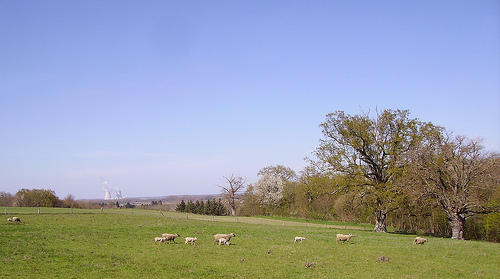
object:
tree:
[393, 130, 500, 241]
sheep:
[413, 237, 429, 245]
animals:
[212, 233, 235, 246]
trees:
[175, 198, 228, 217]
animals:
[154, 232, 201, 245]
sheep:
[294, 237, 308, 244]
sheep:
[336, 233, 356, 246]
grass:
[84, 247, 130, 272]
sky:
[8, 13, 474, 109]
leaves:
[383, 127, 403, 143]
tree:
[295, 105, 462, 234]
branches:
[448, 152, 478, 193]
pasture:
[256, 218, 466, 270]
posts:
[11, 210, 374, 222]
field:
[13, 220, 140, 255]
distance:
[138, 192, 208, 205]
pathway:
[191, 217, 371, 231]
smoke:
[100, 180, 111, 191]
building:
[104, 192, 111, 201]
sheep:
[7, 217, 23, 223]